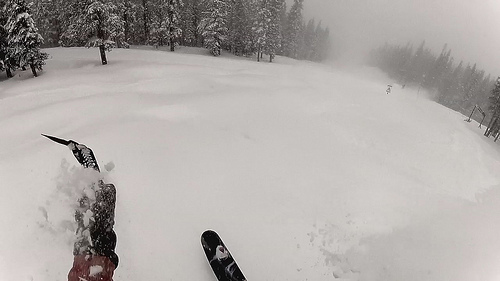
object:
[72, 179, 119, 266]
glove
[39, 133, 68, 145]
pole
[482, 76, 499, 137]
trees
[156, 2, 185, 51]
tree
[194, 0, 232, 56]
tree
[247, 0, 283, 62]
tree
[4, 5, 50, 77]
tree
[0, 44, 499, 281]
snow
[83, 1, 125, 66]
tree